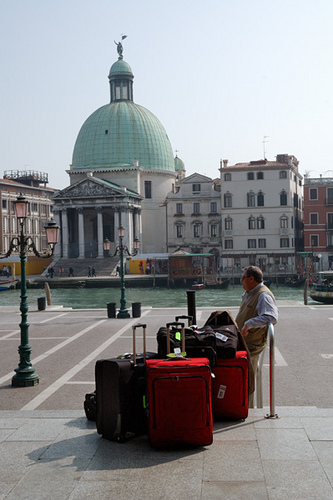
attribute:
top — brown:
[238, 287, 267, 347]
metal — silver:
[267, 324, 284, 419]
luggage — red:
[140, 321, 215, 454]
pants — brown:
[242, 349, 272, 423]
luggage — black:
[91, 341, 153, 441]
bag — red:
[143, 359, 219, 496]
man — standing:
[232, 264, 277, 368]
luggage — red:
[148, 346, 253, 460]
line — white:
[4, 313, 129, 417]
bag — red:
[161, 292, 262, 374]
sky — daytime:
[9, 12, 331, 177]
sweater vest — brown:
[234, 283, 274, 353]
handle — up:
[166, 322, 184, 355]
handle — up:
[132, 322, 147, 364]